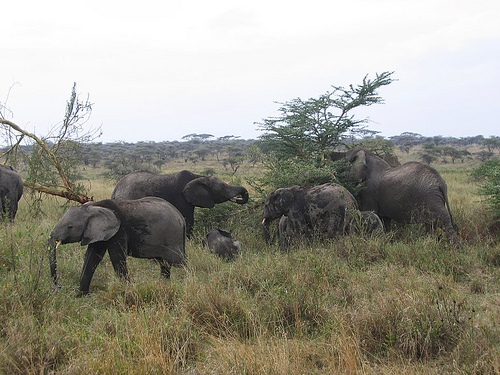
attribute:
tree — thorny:
[251, 70, 399, 163]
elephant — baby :
[196, 225, 244, 264]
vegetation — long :
[0, 62, 497, 374]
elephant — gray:
[108, 166, 234, 255]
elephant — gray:
[115, 164, 250, 256]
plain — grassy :
[6, 176, 490, 373]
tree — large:
[244, 68, 394, 189]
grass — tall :
[14, 172, 499, 372]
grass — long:
[1, 152, 498, 373]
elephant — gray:
[245, 186, 399, 284]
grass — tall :
[304, 250, 394, 319]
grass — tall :
[334, 239, 436, 346]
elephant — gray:
[47, 195, 191, 291]